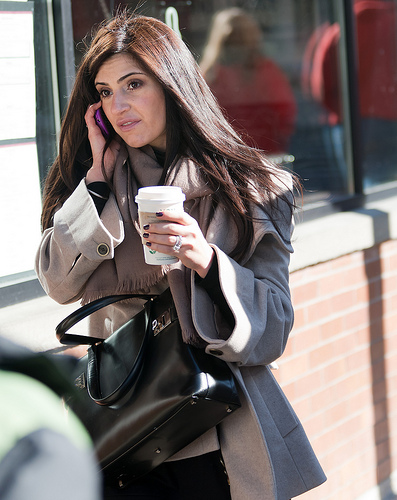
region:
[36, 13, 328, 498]
Woman in front of building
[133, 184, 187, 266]
Paper coffee cup in woman's hand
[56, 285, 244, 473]
Woman's black hangbag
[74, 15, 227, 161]
Woman talking on cell phone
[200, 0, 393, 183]
Two people reflected in glass of window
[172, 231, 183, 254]
Ring on woman's finger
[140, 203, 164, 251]
Painted fingernails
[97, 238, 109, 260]
Round button on coat cuff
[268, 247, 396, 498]
Bricks on side of building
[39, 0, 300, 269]
Woman with long brown hair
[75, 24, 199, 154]
Woman is talking on phone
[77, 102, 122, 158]
Phone next to woman's ear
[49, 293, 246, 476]
Woman has large leather hand bag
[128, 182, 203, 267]
Woman is holding coffee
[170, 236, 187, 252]
Woman has diamond ring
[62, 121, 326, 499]
Woman wearing tan peacoat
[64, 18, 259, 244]
Woman has brown hair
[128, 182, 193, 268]
This is a cup of coffee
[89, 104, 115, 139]
This is a purple cell phone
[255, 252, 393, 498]
Brick building behind woman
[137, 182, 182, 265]
Hand holding coffee cup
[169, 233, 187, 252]
Large diamond ring on finger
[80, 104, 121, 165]
Hand holding cellphone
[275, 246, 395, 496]
Red brick building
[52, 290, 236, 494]
Silver clasped black purse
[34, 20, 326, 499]
Woman taking on phone while holding coffee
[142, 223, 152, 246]
Black finger nail polish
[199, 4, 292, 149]
Blonde woman reflected in window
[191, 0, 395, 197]
Two people reflected in window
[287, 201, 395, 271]
Cement window ledge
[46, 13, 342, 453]
woman with a pink cell phone.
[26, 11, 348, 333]
woman carrying a coffee cup.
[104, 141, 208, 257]
Coffee cup in woman's hand.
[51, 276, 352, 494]
Black purse with the woman.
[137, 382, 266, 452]
Feet on the bottom of the purse.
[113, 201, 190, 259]
Painted nails on the woman.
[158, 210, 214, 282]
Ring on the woman.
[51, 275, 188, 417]
Handle on the purse.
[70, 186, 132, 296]
button on the coat.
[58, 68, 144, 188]
Pink cell phone.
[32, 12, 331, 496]
lady talking on her cell phone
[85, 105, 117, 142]
pink plastic cell phone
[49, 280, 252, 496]
big black leather purse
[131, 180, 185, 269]
disposable white coffee cup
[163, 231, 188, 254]
big shiny engagement ring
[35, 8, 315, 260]
long shiny brown hair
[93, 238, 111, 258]
big black plastic button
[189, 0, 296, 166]
reflection of a person in a red shirt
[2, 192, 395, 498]
short red brick wall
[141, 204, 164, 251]
dark purple painted nails